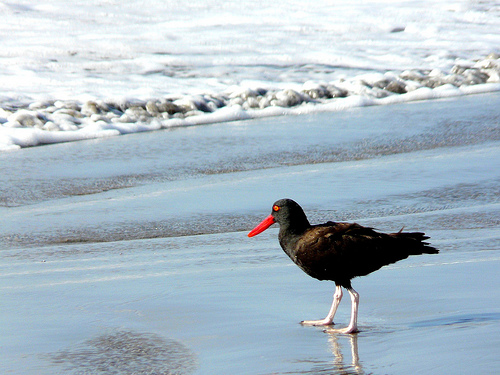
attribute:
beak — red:
[249, 218, 271, 237]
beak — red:
[248, 212, 274, 236]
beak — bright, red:
[220, 197, 295, 268]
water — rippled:
[123, 2, 333, 66]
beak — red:
[245, 207, 289, 235]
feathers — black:
[302, 200, 432, 289]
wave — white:
[4, 3, 496, 155]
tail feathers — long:
[387, 227, 440, 260]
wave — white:
[151, 52, 416, 97]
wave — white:
[101, 88, 173, 116]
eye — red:
[271, 203, 282, 213]